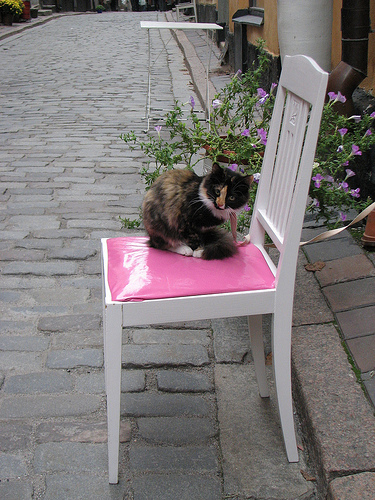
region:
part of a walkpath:
[53, 106, 93, 141]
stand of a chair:
[272, 343, 296, 394]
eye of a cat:
[228, 189, 237, 209]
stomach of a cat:
[147, 202, 180, 236]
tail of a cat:
[216, 232, 239, 251]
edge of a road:
[307, 432, 335, 475]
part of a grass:
[346, 354, 366, 378]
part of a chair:
[207, 265, 232, 279]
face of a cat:
[203, 173, 250, 218]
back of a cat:
[166, 182, 192, 222]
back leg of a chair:
[283, 355, 287, 406]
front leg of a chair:
[110, 330, 118, 388]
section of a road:
[184, 370, 223, 448]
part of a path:
[33, 347, 65, 425]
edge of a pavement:
[310, 379, 325, 432]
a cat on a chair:
[189, 188, 227, 216]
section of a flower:
[238, 86, 256, 112]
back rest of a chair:
[276, 96, 308, 156]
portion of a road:
[52, 99, 77, 134]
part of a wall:
[258, 27, 268, 43]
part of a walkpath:
[30, 60, 79, 117]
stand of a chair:
[99, 419, 125, 467]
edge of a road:
[302, 416, 333, 461]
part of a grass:
[350, 364, 367, 391]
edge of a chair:
[219, 317, 239, 326]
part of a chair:
[188, 273, 208, 283]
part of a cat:
[155, 198, 173, 211]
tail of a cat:
[209, 228, 234, 263]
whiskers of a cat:
[180, 173, 208, 222]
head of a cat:
[212, 153, 240, 192]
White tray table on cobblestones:
[140, 19, 214, 130]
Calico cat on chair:
[141, 162, 251, 258]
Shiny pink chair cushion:
[104, 234, 274, 306]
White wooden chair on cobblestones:
[94, 54, 315, 487]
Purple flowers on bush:
[313, 91, 372, 222]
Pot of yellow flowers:
[0, 1, 21, 28]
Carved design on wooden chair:
[288, 94, 302, 128]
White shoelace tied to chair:
[249, 200, 373, 248]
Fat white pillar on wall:
[274, 1, 333, 81]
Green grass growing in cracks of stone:
[328, 284, 374, 401]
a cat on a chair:
[94, 40, 332, 492]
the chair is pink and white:
[56, 12, 353, 477]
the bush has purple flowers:
[134, 35, 374, 251]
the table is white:
[127, 9, 251, 155]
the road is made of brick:
[8, 8, 175, 209]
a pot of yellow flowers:
[0, 0, 32, 40]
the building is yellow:
[187, 0, 370, 88]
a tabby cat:
[130, 148, 269, 271]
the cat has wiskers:
[192, 176, 255, 228]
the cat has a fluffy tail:
[141, 149, 269, 271]